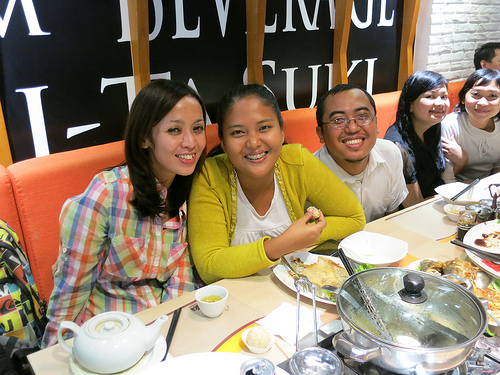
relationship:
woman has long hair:
[385, 69, 467, 212] [397, 71, 445, 192]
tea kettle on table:
[57, 311, 170, 373] [29, 168, 499, 374]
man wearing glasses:
[314, 83, 408, 223] [320, 110, 373, 126]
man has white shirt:
[314, 83, 408, 223] [314, 140, 408, 222]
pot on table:
[333, 268, 488, 373] [29, 168, 499, 374]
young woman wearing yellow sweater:
[187, 84, 367, 287] [189, 145, 363, 284]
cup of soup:
[196, 284, 225, 319] [204, 293, 220, 305]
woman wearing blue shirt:
[385, 69, 467, 212] [385, 124, 450, 211]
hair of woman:
[397, 71, 445, 192] [385, 69, 467, 212]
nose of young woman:
[182, 129, 194, 149] [43, 79, 206, 349]